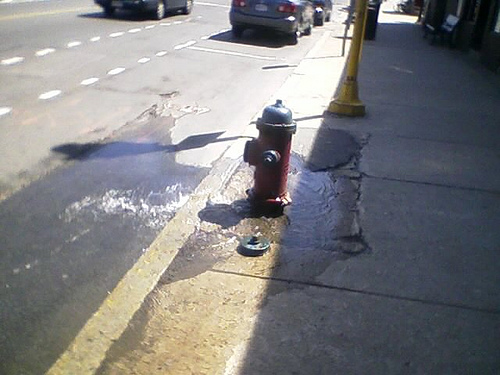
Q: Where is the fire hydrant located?
A: Sidewalk.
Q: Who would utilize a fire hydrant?
A: Firefighters.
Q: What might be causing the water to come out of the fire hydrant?
A: A leak.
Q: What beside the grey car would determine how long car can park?
A: Parking meter.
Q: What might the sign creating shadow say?
A: No parking.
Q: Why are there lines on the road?
A: To guide cars.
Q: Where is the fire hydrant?
A: Sidewalk.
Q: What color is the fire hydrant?
A: Red.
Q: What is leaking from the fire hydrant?
A: Water.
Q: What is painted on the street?
A: Lines.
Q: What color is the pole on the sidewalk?
A: Yellow.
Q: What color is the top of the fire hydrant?
A: Gray.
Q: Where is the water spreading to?
A: Street.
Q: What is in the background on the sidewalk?
A: Bench.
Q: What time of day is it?
A: Mid day.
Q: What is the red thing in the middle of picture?
A: Fire hydrant.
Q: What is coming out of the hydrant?
A: Water.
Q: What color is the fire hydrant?
A: Red and grey.